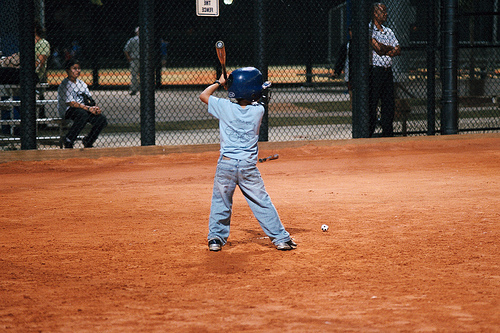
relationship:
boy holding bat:
[197, 38, 301, 257] [214, 37, 237, 93]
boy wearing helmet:
[197, 38, 301, 257] [223, 66, 275, 106]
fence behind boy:
[3, 2, 494, 148] [197, 38, 301, 257]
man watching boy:
[363, 3, 413, 136] [197, 38, 301, 257]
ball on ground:
[317, 222, 333, 233] [6, 160, 495, 329]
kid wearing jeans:
[53, 56, 115, 148] [62, 108, 108, 148]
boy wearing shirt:
[197, 38, 301, 257] [206, 96, 264, 163]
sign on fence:
[181, 0, 231, 25] [3, 2, 494, 148]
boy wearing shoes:
[197, 38, 301, 257] [209, 230, 300, 253]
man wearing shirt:
[363, 3, 413, 136] [362, 25, 397, 70]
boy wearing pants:
[197, 38, 301, 257] [206, 152, 293, 243]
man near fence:
[363, 3, 413, 136] [3, 2, 494, 148]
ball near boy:
[317, 222, 333, 233] [197, 38, 301, 257]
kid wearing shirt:
[53, 56, 115, 148] [57, 77, 95, 112]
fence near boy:
[3, 2, 494, 148] [197, 38, 301, 257]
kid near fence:
[53, 56, 115, 148] [3, 2, 494, 148]